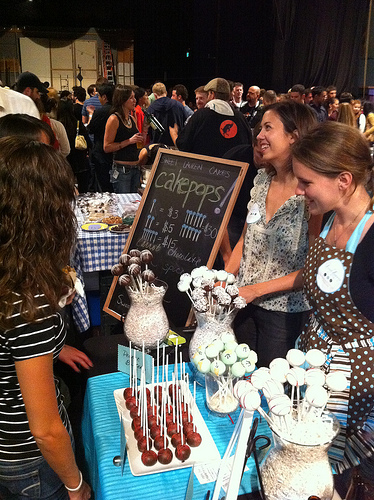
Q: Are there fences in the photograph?
A: No, there are no fences.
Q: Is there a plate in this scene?
A: Yes, there is a plate.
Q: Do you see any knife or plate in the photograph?
A: Yes, there is a plate.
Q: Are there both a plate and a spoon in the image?
A: No, there is a plate but no spoons.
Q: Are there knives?
A: No, there are no knives.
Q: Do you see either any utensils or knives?
A: No, there are no knives or utensils.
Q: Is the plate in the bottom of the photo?
A: Yes, the plate is in the bottom of the image.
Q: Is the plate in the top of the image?
A: No, the plate is in the bottom of the image.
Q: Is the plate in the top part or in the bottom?
A: The plate is in the bottom of the image.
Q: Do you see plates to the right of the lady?
A: Yes, there is a plate to the right of the lady.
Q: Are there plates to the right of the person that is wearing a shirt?
A: Yes, there is a plate to the right of the lady.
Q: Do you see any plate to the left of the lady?
A: No, the plate is to the right of the lady.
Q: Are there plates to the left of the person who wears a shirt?
A: No, the plate is to the right of the lady.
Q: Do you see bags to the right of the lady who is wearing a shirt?
A: No, there is a plate to the right of the lady.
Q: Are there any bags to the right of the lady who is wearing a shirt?
A: No, there is a plate to the right of the lady.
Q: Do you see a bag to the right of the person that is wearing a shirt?
A: No, there is a plate to the right of the lady.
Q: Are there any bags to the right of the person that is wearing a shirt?
A: No, there is a plate to the right of the lady.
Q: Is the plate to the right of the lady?
A: Yes, the plate is to the right of the lady.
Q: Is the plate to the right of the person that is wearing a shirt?
A: Yes, the plate is to the right of the lady.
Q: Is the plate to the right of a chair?
A: No, the plate is to the right of the lady.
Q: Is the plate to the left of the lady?
A: No, the plate is to the right of the lady.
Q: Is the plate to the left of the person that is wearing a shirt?
A: No, the plate is to the right of the lady.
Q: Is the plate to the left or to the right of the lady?
A: The plate is to the right of the lady.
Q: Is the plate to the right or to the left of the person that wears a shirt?
A: The plate is to the right of the lady.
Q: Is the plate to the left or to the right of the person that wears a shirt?
A: The plate is to the right of the lady.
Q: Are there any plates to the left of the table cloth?
A: No, the plate is to the right of the table cloth.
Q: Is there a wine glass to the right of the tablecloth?
A: No, there is a plate to the right of the tablecloth.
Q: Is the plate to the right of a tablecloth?
A: Yes, the plate is to the right of a tablecloth.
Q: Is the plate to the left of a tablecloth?
A: No, the plate is to the right of a tablecloth.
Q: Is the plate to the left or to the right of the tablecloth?
A: The plate is to the right of the tablecloth.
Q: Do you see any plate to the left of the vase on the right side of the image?
A: Yes, there is a plate to the left of the vase.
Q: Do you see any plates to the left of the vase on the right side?
A: Yes, there is a plate to the left of the vase.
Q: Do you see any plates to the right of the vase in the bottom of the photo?
A: No, the plate is to the left of the vase.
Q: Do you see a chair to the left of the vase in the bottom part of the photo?
A: No, there is a plate to the left of the vase.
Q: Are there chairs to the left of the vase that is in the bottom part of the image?
A: No, there is a plate to the left of the vase.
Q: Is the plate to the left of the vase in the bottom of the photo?
A: Yes, the plate is to the left of the vase.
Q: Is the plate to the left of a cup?
A: No, the plate is to the left of the vase.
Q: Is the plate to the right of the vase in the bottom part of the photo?
A: No, the plate is to the left of the vase.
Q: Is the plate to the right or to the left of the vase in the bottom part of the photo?
A: The plate is to the left of the vase.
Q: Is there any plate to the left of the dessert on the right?
A: Yes, there is a plate to the left of the dessert.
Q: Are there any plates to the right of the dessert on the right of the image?
A: No, the plate is to the left of the dessert.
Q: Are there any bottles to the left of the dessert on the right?
A: No, there is a plate to the left of the dessert.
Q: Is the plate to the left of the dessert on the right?
A: Yes, the plate is to the left of the dessert.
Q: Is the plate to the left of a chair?
A: No, the plate is to the left of the dessert.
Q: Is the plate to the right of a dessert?
A: No, the plate is to the left of a dessert.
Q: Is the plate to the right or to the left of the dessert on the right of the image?
A: The plate is to the left of the dessert.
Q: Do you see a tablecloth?
A: Yes, there is a tablecloth.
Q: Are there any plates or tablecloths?
A: Yes, there is a tablecloth.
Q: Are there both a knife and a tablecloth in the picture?
A: No, there is a tablecloth but no knives.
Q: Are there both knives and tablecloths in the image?
A: No, there is a tablecloth but no knives.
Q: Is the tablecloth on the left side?
A: Yes, the tablecloth is on the left of the image.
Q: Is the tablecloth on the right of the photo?
A: No, the tablecloth is on the left of the image.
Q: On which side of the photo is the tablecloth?
A: The tablecloth is on the left of the image.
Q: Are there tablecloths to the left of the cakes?
A: Yes, there is a tablecloth to the left of the cakes.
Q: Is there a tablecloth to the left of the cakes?
A: Yes, there is a tablecloth to the left of the cakes.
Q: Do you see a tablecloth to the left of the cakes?
A: Yes, there is a tablecloth to the left of the cakes.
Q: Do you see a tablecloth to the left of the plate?
A: Yes, there is a tablecloth to the left of the plate.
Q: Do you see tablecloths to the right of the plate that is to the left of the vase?
A: No, the tablecloth is to the left of the plate.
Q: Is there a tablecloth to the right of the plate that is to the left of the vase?
A: No, the tablecloth is to the left of the plate.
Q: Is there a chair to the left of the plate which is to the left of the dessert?
A: No, there is a tablecloth to the left of the plate.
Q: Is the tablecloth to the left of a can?
A: No, the tablecloth is to the left of the plate.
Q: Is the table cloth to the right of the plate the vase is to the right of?
A: No, the table cloth is to the left of the plate.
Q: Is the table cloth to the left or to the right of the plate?
A: The table cloth is to the left of the plate.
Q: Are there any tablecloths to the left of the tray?
A: Yes, there is a tablecloth to the left of the tray.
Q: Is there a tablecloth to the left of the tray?
A: Yes, there is a tablecloth to the left of the tray.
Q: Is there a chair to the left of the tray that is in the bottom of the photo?
A: No, there is a tablecloth to the left of the tray.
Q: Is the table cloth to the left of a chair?
A: No, the table cloth is to the left of the tray.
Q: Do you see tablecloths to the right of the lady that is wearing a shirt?
A: Yes, there is a tablecloth to the right of the lady.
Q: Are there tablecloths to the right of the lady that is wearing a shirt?
A: Yes, there is a tablecloth to the right of the lady.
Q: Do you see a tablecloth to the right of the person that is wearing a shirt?
A: Yes, there is a tablecloth to the right of the lady.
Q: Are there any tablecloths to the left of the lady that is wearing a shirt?
A: No, the tablecloth is to the right of the lady.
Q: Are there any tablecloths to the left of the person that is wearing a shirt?
A: No, the tablecloth is to the right of the lady.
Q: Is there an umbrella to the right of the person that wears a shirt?
A: No, there is a tablecloth to the right of the lady.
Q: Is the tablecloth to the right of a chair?
A: No, the tablecloth is to the right of a lady.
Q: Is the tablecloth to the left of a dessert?
A: Yes, the tablecloth is to the left of a dessert.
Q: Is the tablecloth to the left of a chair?
A: No, the tablecloth is to the left of a dessert.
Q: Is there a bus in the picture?
A: No, there are no buses.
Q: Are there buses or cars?
A: No, there are no buses or cars.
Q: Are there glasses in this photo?
A: No, there are no glasses.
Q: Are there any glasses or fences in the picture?
A: No, there are no glasses or fences.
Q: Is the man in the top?
A: Yes, the man is in the top of the image.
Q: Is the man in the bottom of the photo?
A: No, the man is in the top of the image.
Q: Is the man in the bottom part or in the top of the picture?
A: The man is in the top of the image.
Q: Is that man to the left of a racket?
A: No, the man is to the left of a person.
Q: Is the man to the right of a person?
A: No, the man is to the left of a person.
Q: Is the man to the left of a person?
A: Yes, the man is to the left of a person.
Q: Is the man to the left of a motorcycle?
A: No, the man is to the left of a person.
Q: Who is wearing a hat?
A: The man is wearing a hat.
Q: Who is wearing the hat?
A: The man is wearing a hat.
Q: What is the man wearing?
A: The man is wearing a hat.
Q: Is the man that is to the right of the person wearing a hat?
A: Yes, the man is wearing a hat.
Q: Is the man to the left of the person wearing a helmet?
A: No, the man is wearing a hat.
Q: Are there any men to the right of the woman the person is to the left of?
A: Yes, there is a man to the right of the woman.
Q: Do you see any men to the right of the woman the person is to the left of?
A: Yes, there is a man to the right of the woman.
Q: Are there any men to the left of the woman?
A: No, the man is to the right of the woman.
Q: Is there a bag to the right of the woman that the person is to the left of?
A: No, there is a man to the right of the woman.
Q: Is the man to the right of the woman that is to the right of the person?
A: Yes, the man is to the right of the woman.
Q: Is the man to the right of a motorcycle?
A: No, the man is to the right of the woman.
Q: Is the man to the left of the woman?
A: No, the man is to the right of the woman.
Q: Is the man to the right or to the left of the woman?
A: The man is to the right of the woman.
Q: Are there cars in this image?
A: No, there are no cars.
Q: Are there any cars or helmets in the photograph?
A: No, there are no cars or helmets.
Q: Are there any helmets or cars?
A: No, there are no cars or helmets.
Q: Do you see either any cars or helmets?
A: No, there are no cars or helmets.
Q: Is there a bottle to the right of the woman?
A: No, there is a person to the right of the woman.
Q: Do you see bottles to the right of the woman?
A: No, there is a person to the right of the woman.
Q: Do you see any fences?
A: No, there are no fences.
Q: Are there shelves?
A: No, there are no shelves.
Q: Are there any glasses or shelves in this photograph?
A: No, there are no shelves or glasses.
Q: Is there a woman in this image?
A: Yes, there is a woman.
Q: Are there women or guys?
A: Yes, there is a woman.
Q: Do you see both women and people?
A: Yes, there are both a woman and a person.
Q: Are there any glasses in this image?
A: No, there are no glasses.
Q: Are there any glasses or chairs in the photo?
A: No, there are no glasses or chairs.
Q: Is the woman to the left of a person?
A: No, the woman is to the right of a person.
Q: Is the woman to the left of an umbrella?
A: No, the woman is to the left of a person.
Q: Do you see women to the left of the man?
A: Yes, there is a woman to the left of the man.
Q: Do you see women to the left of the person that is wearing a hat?
A: Yes, there is a woman to the left of the man.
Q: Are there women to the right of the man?
A: No, the woman is to the left of the man.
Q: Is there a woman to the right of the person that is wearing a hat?
A: No, the woman is to the left of the man.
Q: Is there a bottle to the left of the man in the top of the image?
A: No, there is a woman to the left of the man.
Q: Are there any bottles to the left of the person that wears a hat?
A: No, there is a woman to the left of the man.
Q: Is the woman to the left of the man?
A: Yes, the woman is to the left of the man.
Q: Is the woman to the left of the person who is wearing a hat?
A: Yes, the woman is to the left of the man.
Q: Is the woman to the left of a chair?
A: No, the woman is to the left of the man.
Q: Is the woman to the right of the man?
A: No, the woman is to the left of the man.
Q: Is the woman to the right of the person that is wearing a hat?
A: No, the woman is to the left of the man.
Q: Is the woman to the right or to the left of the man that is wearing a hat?
A: The woman is to the left of the man.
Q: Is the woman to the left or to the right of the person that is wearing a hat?
A: The woman is to the left of the man.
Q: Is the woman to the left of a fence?
A: No, the woman is to the left of a person.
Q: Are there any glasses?
A: No, there are no glasses.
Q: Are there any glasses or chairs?
A: No, there are no glasses or chairs.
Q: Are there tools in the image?
A: No, there are no tools.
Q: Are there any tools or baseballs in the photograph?
A: No, there are no tools or baseballs.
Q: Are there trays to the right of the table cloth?
A: Yes, there is a tray to the right of the table cloth.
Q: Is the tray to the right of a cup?
A: No, the tray is to the right of the tablecloth.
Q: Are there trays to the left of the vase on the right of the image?
A: Yes, there is a tray to the left of the vase.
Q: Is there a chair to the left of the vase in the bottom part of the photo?
A: No, there is a tray to the left of the vase.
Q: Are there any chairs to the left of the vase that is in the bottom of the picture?
A: No, there is a tray to the left of the vase.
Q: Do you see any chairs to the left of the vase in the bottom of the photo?
A: No, there is a tray to the left of the vase.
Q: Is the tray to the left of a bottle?
A: No, the tray is to the left of the vase.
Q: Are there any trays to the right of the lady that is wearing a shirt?
A: Yes, there is a tray to the right of the lady.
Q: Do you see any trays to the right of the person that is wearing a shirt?
A: Yes, there is a tray to the right of the lady.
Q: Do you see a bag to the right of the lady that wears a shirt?
A: No, there is a tray to the right of the lady.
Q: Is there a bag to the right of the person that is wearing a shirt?
A: No, there is a tray to the right of the lady.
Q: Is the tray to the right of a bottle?
A: No, the tray is to the right of the lady.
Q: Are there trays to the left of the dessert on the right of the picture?
A: Yes, there is a tray to the left of the dessert.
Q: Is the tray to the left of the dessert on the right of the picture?
A: Yes, the tray is to the left of the dessert.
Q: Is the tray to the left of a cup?
A: No, the tray is to the left of the dessert.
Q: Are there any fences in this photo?
A: No, there are no fences.